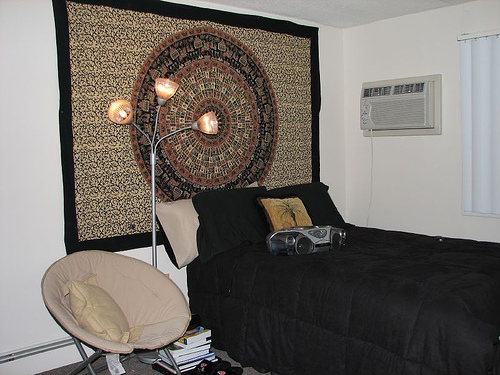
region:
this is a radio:
[263, 217, 348, 258]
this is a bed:
[210, 247, 473, 364]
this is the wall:
[356, 155, 436, 215]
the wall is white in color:
[382, 149, 433, 215]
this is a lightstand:
[115, 77, 209, 252]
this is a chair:
[52, 250, 187, 347]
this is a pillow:
[70, 285, 127, 340]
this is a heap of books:
[186, 330, 216, 365]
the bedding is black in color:
[369, 240, 449, 365]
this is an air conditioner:
[361, 86, 438, 136]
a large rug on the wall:
[57, 2, 320, 235]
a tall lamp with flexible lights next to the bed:
[83, 72, 219, 316]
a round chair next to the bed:
[48, 254, 185, 374]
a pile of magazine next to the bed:
[167, 335, 219, 372]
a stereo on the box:
[266, 222, 351, 261]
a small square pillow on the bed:
[253, 195, 311, 239]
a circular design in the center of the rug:
[131, 32, 276, 208]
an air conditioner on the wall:
[362, 77, 442, 134]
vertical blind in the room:
[458, 35, 498, 247]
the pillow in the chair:
[69, 280, 134, 338]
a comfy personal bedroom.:
[26, 27, 481, 362]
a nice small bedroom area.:
[30, 23, 475, 358]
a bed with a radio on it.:
[170, 175, 466, 356]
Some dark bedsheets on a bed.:
[250, 247, 476, 356]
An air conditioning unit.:
[335, 60, 452, 140]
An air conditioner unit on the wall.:
[327, 36, 467, 191]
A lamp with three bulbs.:
[90, 72, 227, 189]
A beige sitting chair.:
[22, 241, 204, 361]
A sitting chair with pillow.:
[28, 244, 189, 354]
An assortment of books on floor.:
[142, 326, 232, 368]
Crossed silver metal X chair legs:
[70, 338, 102, 373]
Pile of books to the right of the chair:
[153, 324, 224, 372]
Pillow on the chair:
[59, 281, 131, 345]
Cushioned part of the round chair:
[40, 249, 190, 351]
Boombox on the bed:
[261, 222, 351, 257]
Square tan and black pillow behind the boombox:
[259, 195, 316, 227]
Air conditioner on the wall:
[358, 74, 445, 134]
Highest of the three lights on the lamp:
[151, 72, 180, 101]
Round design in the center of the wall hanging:
[128, 26, 279, 199]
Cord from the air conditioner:
[365, 137, 380, 227]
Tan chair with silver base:
[31, 240, 304, 360]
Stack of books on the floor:
[158, 315, 231, 373]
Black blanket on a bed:
[212, 198, 464, 370]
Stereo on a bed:
[261, 213, 383, 257]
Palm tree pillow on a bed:
[260, 189, 327, 244]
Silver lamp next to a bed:
[80, 50, 233, 293]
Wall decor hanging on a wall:
[52, 8, 352, 230]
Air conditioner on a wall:
[350, 73, 472, 147]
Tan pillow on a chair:
[48, 281, 155, 360]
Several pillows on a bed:
[151, 192, 331, 264]